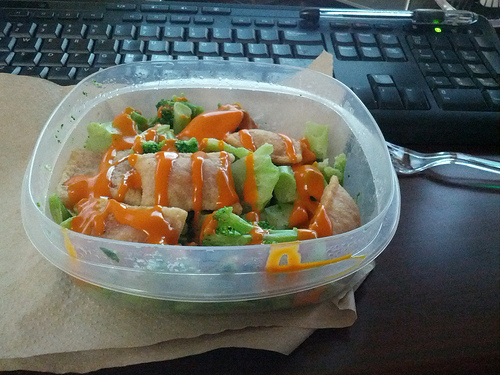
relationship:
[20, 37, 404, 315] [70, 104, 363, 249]
bowl filled with food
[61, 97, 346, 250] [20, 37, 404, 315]
broccoli in bowl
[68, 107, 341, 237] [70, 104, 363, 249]
dressing on food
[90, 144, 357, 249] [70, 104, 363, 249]
dumplings in food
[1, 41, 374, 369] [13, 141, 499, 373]
napkin on desk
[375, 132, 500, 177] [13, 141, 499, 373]
fork lying on desk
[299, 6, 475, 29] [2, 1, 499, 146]
pen lying on keyboard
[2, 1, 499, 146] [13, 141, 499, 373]
keyboard sitting on desk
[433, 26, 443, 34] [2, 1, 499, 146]
light on keyboard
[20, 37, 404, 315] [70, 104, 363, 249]
bowl of food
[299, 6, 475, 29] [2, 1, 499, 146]
pen on keyboard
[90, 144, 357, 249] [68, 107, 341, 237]
dumplings under dressing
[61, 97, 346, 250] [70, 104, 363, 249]
broccoli mixed with food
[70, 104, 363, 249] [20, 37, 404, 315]
food in bowl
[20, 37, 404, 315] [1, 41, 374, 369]
bowl on napkin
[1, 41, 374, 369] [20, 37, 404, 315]
napkin under bowl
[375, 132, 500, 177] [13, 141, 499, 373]
fork on desk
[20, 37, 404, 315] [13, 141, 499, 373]
bowl on desk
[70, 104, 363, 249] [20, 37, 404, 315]
food on bowl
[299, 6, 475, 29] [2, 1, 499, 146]
pen laying on top of keyboard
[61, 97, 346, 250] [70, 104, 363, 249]
broccoli in food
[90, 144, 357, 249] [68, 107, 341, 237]
dumplings with dressing